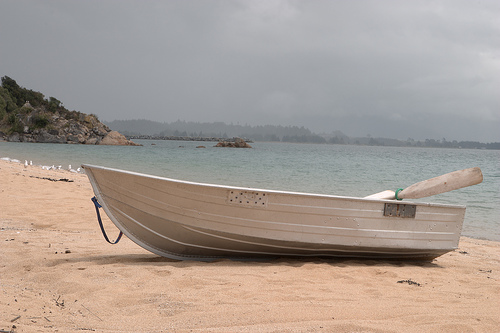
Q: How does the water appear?
A: Calm.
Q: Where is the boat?
A: On the sand.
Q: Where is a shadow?
A: On sand.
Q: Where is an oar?
A: In the boat.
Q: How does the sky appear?
A: Overcast.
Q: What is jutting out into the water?
A: Rocks.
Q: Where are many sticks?
A: On the sand.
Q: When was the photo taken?
A: During the daytime.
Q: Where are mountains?
A: In the distance.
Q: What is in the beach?
A: Water.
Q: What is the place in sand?
A: Beach.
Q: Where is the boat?
A: Beach.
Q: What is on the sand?
A: Water.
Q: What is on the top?
A: Sky.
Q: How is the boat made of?
A: Aluminum.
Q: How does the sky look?
A: Grey and stormy.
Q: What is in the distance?
A: Mountains.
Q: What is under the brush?
A: Rocks.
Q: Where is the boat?
A: Shore.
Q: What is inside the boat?
A: An ore.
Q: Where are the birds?
A: On the left.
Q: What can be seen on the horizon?
A: Mountains.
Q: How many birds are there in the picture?
A: Six.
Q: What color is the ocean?
A: Blue.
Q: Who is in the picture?
A: No one.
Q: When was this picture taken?
A: Daytime.